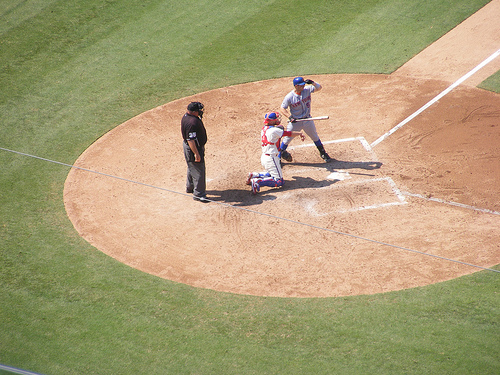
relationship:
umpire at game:
[177, 100, 214, 206] [2, 2, 499, 343]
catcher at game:
[245, 109, 308, 201] [2, 2, 499, 343]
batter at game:
[272, 66, 343, 173] [2, 2, 499, 343]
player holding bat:
[279, 76, 327, 162] [286, 112, 331, 125]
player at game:
[279, 76, 327, 162] [2, 2, 499, 343]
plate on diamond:
[327, 166, 355, 183] [263, 1, 500, 224]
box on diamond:
[261, 93, 416, 221] [263, 1, 500, 224]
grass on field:
[2, 0, 500, 375] [1, 1, 498, 365]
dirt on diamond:
[55, 1, 499, 296] [263, 1, 500, 224]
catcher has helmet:
[245, 109, 308, 201] [263, 112, 283, 129]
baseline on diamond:
[367, 17, 499, 222] [263, 1, 500, 224]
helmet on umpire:
[182, 98, 210, 120] [177, 100, 214, 206]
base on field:
[315, 163, 363, 188] [1, 1, 498, 365]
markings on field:
[0, 59, 499, 220] [1, 1, 498, 365]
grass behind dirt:
[2, 0, 500, 375] [55, 1, 499, 296]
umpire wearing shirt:
[177, 100, 214, 206] [175, 110, 211, 151]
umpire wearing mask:
[177, 100, 214, 206] [196, 102, 206, 120]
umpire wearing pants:
[177, 100, 214, 206] [177, 141, 209, 201]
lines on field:
[370, 17, 500, 229] [1, 1, 498, 365]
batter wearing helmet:
[272, 66, 343, 173] [284, 75, 309, 92]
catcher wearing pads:
[245, 109, 308, 201] [275, 178, 285, 188]